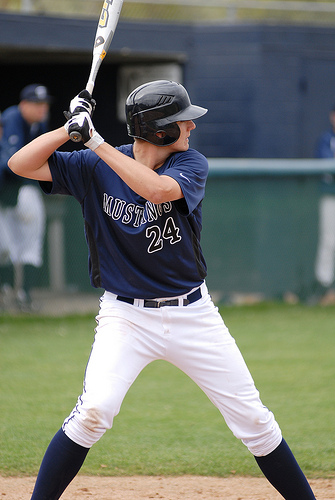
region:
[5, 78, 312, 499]
Baseball player batting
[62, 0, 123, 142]
Silver baseball bat held by player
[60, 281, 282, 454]
White pants worn by baseball player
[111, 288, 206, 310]
Black belt on baseball player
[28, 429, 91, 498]
Blue sock worn by baseball player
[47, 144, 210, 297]
Blue jersey worn by baseball player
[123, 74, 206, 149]
Black helmet worn by baseball batter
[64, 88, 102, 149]
Black and white batting gloves worn by player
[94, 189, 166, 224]
Team name, "Mustangs" on baseball jersey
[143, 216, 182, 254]
White stitched "24" on baseball jersey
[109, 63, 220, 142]
player wearing a helmet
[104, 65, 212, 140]
the helmet is black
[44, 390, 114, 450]
a stain on the knee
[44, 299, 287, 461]
the pants are white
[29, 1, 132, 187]
the player is holding a bat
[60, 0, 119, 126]
the bat is grey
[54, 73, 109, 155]
the gloves are black and white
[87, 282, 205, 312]
the belt is blue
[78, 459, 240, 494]
the dirt is light brown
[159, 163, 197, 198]
a white nike swoosh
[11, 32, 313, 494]
baseball player ready to swing his bat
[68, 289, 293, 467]
white baseball pants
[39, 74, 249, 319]
baseball player wearing his uniform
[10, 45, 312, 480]
young man wearing white and blue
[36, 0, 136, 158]
silver bat with writing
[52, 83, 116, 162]
white and black gloves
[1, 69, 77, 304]
man standing over a fence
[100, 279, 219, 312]
thin belt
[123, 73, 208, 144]
shiny black helmet with hood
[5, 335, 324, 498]
grass and sand on the field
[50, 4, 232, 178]
a man holding a baseball bat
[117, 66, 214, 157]
a man wearing a black helmet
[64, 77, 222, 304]
a man wearing a blue shirt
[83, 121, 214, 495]
a man wearing white base ball pants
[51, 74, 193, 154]
a man wearing black and white gloves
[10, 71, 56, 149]
a man wearing a base ball cap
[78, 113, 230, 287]
a man with white letters and numbers a shirt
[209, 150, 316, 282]
a fence covered with a green tarp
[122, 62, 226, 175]
a man with his head turned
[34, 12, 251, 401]
a man playing baseball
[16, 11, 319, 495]
a man is batting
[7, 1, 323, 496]
a ma holding a bat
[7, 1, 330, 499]
a man holding bat in the air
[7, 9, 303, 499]
a man wearing a uniform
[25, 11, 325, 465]
a man wearing a baseball uniform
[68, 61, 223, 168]
a man wearing a helmet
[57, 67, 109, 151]
a man wearing gloves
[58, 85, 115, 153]
a man wearing black and white gloves